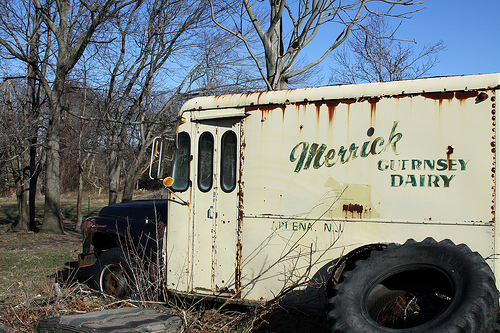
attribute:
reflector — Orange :
[137, 159, 191, 206]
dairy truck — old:
[75, 74, 498, 325]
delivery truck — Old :
[160, 71, 498, 311]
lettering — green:
[291, 118, 406, 171]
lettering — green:
[377, 155, 469, 174]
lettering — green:
[390, 172, 454, 189]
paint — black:
[84, 195, 171, 287]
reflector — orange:
[161, 175, 179, 187]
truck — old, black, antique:
[78, 72, 498, 312]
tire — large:
[325, 237, 494, 329]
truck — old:
[46, 49, 494, 317]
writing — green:
[285, 119, 472, 193]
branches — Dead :
[183, 185, 361, 331]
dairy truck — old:
[130, 73, 487, 239]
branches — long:
[325, 8, 446, 83]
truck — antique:
[168, 66, 495, 314]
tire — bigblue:
[307, 207, 474, 331]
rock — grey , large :
[33, 304, 188, 331]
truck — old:
[146, 72, 498, 310]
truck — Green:
[190, 101, 447, 237]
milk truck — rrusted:
[78, 71, 499, 310]